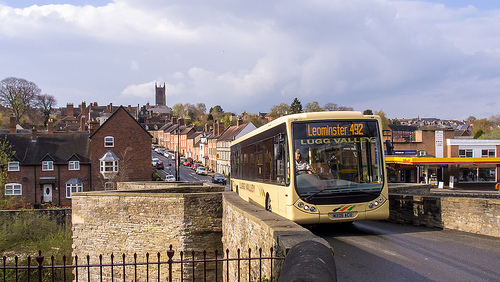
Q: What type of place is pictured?
A: It is a road.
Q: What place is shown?
A: It is a road.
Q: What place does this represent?
A: It represents the road.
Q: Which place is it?
A: It is a road.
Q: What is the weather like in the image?
A: It is overcast.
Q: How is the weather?
A: It is overcast.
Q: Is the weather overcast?
A: Yes, it is overcast.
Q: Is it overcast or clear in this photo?
A: It is overcast.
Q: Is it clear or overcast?
A: It is overcast.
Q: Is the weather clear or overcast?
A: It is overcast.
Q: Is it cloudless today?
A: No, it is overcast.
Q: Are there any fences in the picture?
A: Yes, there is a fence.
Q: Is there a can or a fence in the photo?
A: Yes, there is a fence.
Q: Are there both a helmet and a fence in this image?
A: No, there is a fence but no helmets.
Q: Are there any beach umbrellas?
A: No, there are no beach umbrellas.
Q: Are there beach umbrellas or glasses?
A: No, there are no beach umbrellas or glasses.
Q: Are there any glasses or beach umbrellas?
A: No, there are no beach umbrellas or glasses.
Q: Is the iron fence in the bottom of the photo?
A: Yes, the fence is in the bottom of the image.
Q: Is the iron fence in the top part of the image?
A: No, the fence is in the bottom of the image.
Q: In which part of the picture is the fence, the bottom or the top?
A: The fence is in the bottom of the image.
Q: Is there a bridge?
A: Yes, there is a bridge.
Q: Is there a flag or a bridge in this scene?
A: Yes, there is a bridge.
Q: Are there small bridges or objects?
A: Yes, there is a small bridge.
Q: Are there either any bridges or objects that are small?
A: Yes, the bridge is small.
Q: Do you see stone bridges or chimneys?
A: Yes, there is a stone bridge.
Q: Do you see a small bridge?
A: Yes, there is a small bridge.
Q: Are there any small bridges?
A: Yes, there is a small bridge.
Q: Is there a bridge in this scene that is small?
A: Yes, there is a bridge that is small.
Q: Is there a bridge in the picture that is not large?
A: Yes, there is a small bridge.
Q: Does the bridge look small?
A: Yes, the bridge is small.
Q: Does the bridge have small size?
A: Yes, the bridge is small.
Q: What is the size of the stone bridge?
A: The bridge is small.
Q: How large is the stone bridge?
A: The bridge is small.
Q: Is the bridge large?
A: No, the bridge is small.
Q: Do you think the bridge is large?
A: No, the bridge is small.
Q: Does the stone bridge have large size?
A: No, the bridge is small.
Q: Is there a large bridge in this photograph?
A: No, there is a bridge but it is small.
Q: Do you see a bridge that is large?
A: No, there is a bridge but it is small.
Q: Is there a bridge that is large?
A: No, there is a bridge but it is small.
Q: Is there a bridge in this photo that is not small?
A: No, there is a bridge but it is small.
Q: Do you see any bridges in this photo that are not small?
A: No, there is a bridge but it is small.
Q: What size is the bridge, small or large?
A: The bridge is small.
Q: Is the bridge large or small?
A: The bridge is small.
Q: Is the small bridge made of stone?
A: Yes, the bridge is made of stone.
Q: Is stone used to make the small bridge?
A: Yes, the bridge is made of stone.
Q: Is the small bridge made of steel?
A: No, the bridge is made of stone.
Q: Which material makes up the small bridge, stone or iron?
A: The bridge is made of stone.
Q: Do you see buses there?
A: Yes, there is a bus.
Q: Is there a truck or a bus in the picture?
A: Yes, there is a bus.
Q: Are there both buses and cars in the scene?
A: Yes, there are both a bus and a car.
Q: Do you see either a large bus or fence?
A: Yes, there is a large bus.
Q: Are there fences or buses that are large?
A: Yes, the bus is large.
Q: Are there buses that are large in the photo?
A: Yes, there is a large bus.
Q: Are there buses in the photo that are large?
A: Yes, there is a bus that is large.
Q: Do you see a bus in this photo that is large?
A: Yes, there is a bus that is large.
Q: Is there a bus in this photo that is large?
A: Yes, there is a bus that is large.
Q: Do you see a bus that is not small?
A: Yes, there is a large bus.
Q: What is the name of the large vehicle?
A: The vehicle is a bus.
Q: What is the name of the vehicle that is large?
A: The vehicle is a bus.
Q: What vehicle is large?
A: The vehicle is a bus.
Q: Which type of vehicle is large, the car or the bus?
A: The bus is large.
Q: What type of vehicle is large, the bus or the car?
A: The bus is large.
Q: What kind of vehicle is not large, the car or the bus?
A: The car is not large.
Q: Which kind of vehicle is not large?
A: The vehicle is a car.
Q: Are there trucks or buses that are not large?
A: No, there is a bus but it is large.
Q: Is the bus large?
A: Yes, the bus is large.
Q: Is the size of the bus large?
A: Yes, the bus is large.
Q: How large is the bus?
A: The bus is large.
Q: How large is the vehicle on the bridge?
A: The bus is large.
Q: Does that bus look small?
A: No, the bus is large.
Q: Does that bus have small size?
A: No, the bus is large.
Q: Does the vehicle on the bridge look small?
A: No, the bus is large.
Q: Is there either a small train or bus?
A: No, there is a bus but it is large.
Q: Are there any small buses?
A: No, there is a bus but it is large.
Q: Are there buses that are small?
A: No, there is a bus but it is large.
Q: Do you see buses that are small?
A: No, there is a bus but it is large.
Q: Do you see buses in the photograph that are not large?
A: No, there is a bus but it is large.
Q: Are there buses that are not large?
A: No, there is a bus but it is large.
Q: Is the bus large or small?
A: The bus is large.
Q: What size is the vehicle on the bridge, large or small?
A: The bus is large.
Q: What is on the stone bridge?
A: The bus is on the bridge.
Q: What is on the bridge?
A: The bus is on the bridge.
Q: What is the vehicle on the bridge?
A: The vehicle is a bus.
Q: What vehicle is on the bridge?
A: The vehicle is a bus.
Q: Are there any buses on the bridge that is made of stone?
A: Yes, there is a bus on the bridge.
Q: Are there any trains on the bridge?
A: No, there is a bus on the bridge.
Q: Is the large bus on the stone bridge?
A: Yes, the bus is on the bridge.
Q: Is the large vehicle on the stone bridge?
A: Yes, the bus is on the bridge.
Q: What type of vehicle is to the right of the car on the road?
A: The vehicle is a bus.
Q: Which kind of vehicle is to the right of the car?
A: The vehicle is a bus.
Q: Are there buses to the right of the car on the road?
A: Yes, there is a bus to the right of the car.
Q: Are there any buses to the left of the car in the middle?
A: No, the bus is to the right of the car.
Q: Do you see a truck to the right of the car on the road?
A: No, there is a bus to the right of the car.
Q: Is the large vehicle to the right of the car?
A: Yes, the bus is to the right of the car.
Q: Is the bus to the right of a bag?
A: No, the bus is to the right of the car.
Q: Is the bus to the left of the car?
A: No, the bus is to the right of the car.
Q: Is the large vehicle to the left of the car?
A: No, the bus is to the right of the car.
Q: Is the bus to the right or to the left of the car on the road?
A: The bus is to the right of the car.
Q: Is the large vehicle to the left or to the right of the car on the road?
A: The bus is to the right of the car.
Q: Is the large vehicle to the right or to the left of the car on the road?
A: The bus is to the right of the car.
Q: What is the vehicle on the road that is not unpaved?
A: The vehicle is a bus.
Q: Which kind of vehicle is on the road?
A: The vehicle is a bus.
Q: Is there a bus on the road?
A: Yes, there is a bus on the road.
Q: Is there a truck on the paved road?
A: No, there is a bus on the road.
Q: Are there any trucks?
A: No, there are no trucks.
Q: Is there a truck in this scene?
A: No, there are no trucks.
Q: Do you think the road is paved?
A: Yes, the road is paved.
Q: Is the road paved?
A: Yes, the road is paved.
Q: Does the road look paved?
A: Yes, the road is paved.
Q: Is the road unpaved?
A: No, the road is paved.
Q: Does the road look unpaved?
A: No, the road is paved.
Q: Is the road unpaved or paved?
A: The road is paved.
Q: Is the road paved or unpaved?
A: The road is paved.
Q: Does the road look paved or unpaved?
A: The road is paved.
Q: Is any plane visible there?
A: No, there are no airplanes.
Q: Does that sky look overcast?
A: Yes, the sky is overcast.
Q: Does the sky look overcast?
A: Yes, the sky is overcast.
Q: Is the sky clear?
A: No, the sky is overcast.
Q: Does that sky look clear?
A: No, the sky is overcast.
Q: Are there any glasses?
A: No, there are no glasses.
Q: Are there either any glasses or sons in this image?
A: No, there are no glasses or sons.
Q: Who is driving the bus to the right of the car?
A: The man is driving the bus.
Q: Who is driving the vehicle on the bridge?
A: The man is driving the bus.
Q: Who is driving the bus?
A: The man is driving the bus.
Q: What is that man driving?
A: The man is driving the bus.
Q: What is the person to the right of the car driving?
A: The man is driving the bus.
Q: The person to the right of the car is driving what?
A: The man is driving the bus.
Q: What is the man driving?
A: The man is driving the bus.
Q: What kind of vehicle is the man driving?
A: The man is driving the bus.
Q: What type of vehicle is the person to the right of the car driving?
A: The man is driving the bus.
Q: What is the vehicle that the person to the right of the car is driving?
A: The vehicle is a bus.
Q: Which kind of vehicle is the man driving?
A: The man is driving the bus.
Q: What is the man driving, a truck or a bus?
A: The man is driving a bus.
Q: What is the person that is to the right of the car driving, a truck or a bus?
A: The man is driving a bus.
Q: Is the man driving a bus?
A: Yes, the man is driving a bus.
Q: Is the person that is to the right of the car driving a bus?
A: Yes, the man is driving a bus.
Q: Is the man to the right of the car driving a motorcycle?
A: No, the man is driving a bus.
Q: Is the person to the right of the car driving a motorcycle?
A: No, the man is driving a bus.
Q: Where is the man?
A: The man is on the bus.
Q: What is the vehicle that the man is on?
A: The vehicle is a bus.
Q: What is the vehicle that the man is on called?
A: The vehicle is a bus.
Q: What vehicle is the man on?
A: The man is on the bus.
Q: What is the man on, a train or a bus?
A: The man is on a bus.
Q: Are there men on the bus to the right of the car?
A: Yes, there is a man on the bus.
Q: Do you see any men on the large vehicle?
A: Yes, there is a man on the bus.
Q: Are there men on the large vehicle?
A: Yes, there is a man on the bus.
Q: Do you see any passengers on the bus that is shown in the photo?
A: No, there is a man on the bus.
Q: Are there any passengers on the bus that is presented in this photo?
A: No, there is a man on the bus.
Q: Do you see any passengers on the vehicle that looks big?
A: No, there is a man on the bus.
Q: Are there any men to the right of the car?
A: Yes, there is a man to the right of the car.